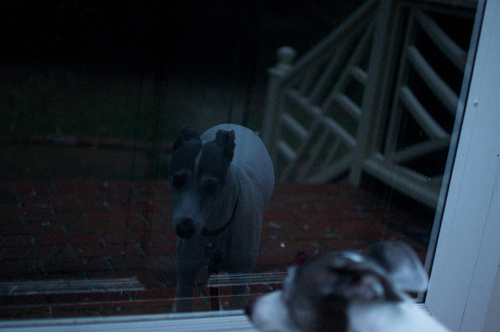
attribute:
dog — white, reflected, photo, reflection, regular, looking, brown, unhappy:
[251, 245, 446, 329]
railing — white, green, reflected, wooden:
[400, 31, 453, 79]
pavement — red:
[58, 228, 122, 265]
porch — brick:
[8, 233, 60, 271]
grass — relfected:
[94, 94, 117, 107]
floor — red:
[82, 178, 116, 195]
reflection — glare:
[139, 10, 190, 42]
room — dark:
[243, 5, 380, 81]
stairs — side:
[262, 102, 346, 170]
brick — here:
[75, 132, 114, 143]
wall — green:
[219, 27, 255, 55]